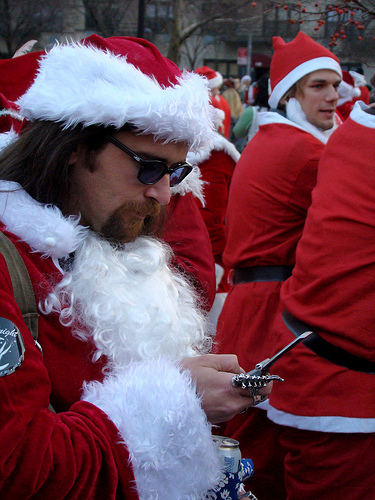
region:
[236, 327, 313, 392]
gray and black flip phone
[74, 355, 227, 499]
white fur cuffs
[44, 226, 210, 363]
Santa Clause white beard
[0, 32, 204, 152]
Red and white Santa Clause dress up hat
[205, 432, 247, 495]
a white can of soda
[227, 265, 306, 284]
a black belt around a mans waist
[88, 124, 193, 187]
man wearing black sunglasses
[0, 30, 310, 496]
Man in a Santa Clause suit looking at his phone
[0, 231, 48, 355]
brown shoulder strap to a backpack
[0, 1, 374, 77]
Brown and black brick building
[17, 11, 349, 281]
fake Santa's gathered together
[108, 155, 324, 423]
this Santa is checking his phone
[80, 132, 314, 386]
this Santa is texting someone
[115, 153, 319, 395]
Santa is receiving a call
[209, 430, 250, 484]
Santa has a can on his body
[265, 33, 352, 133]
this is a young Kris Kringle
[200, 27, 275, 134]
a lot of Santa's in the background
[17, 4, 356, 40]
buildings in the background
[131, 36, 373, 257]
red and white Santa suites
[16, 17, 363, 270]
these guys work for some type of holiday organization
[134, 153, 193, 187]
Part of bearded santa's glasses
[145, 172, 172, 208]
Nose of bearded santa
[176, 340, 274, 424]
Hand of bearded santa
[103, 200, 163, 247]
Beard of y oung santa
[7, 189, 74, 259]
Part of fur collar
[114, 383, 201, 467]
Part of fur cuff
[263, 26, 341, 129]
Head of young santa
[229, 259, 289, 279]
Black belt of santa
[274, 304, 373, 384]
Black belt of santa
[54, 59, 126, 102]
White fur on santa hat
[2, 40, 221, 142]
the red and white santa hat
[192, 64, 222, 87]
the red and white santa hat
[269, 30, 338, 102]
the red and white santa hat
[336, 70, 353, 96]
the red and white santa hat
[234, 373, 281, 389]
the long black weird ring of santa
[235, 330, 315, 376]
the flip phone of santa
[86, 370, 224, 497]
the fluffy white cuff of the jacket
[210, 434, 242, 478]
the metal can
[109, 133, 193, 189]
the black sunglasses of santa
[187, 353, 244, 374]
the thumb of a hand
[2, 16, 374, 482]
group of people dressed up like santa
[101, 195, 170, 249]
man has brown goatee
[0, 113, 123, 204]
man has brown hair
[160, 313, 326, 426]
man holding cell phone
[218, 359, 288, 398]
man wearing silver ring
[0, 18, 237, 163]
hat has white fur trim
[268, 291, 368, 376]
person wearing black belt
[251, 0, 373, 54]
tree limbs with red bulbs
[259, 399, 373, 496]
person wearing red pants